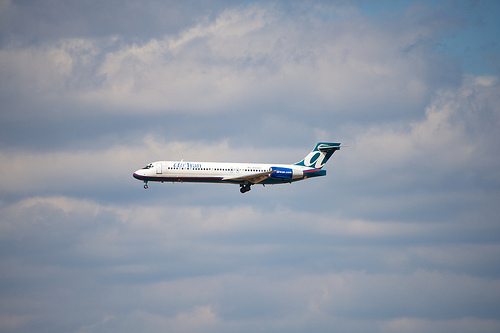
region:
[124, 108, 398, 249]
plane in the air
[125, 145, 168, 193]
front of the plane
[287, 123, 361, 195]
tail of the plane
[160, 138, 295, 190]
windows on side of plane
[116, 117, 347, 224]
blue and white plane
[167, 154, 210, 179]
writing on side of plane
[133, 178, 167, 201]
wheel of the plane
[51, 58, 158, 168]
clouds in the sky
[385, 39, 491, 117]
blue sky behind clouds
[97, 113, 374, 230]
one plane in the air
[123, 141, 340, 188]
a white and red and blue plane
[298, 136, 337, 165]
the tail of a plane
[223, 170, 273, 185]
the wing of a plane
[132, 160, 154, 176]
the nose of a plane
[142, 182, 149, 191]
the landing tire of a plane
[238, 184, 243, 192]
the landing tire of a plane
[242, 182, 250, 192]
the landing tire of a plane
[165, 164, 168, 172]
the small window of a plane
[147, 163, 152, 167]
the small window of a plane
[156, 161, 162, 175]
the white door of a plane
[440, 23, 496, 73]
the patch of blue sky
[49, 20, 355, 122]
clouds in the sky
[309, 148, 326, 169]
the logo on the plane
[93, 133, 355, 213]
plane in the sky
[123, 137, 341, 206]
the plane is flying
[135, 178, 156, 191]
the landing gear is down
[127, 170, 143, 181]
the nose of the plane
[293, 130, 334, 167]
tail of the plane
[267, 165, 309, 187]
engine of the plane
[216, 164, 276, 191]
wing of the plane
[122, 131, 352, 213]
a plane is preparing to land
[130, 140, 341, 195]
the wheels are down to land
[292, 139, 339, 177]
a logo is on the plane's tail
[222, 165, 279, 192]
the flaps are down on the wings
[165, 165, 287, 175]
windows are along the fuselage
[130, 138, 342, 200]
the plane is a passenger jet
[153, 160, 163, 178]
a door is behind the cockpit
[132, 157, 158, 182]
windows are in the cockpit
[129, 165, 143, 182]
the nose of the jet is black and white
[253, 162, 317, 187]
the jet engine is blue and white